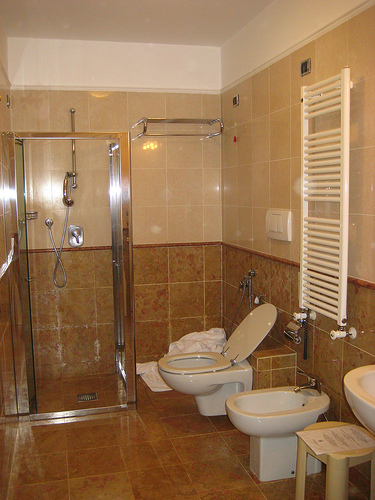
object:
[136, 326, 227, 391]
towels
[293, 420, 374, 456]
paper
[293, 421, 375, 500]
stool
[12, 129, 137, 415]
shower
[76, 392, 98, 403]
drain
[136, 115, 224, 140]
bar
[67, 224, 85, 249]
handle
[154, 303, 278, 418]
toilet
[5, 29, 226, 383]
wall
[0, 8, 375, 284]
tile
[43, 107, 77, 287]
hose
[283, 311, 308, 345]
toilet roll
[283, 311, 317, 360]
dispenser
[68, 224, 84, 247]
valve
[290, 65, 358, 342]
vents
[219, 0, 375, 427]
wall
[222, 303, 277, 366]
lid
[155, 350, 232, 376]
sit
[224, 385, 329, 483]
sink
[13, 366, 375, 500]
floor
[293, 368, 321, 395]
faucet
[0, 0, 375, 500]
bathroom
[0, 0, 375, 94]
ceiling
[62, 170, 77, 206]
hand sprayer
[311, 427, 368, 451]
black words